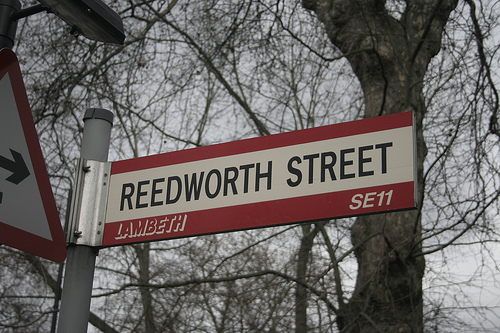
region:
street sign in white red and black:
[103, 128, 420, 246]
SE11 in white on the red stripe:
[328, 183, 405, 219]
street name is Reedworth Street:
[118, 139, 418, 211]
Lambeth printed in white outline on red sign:
[104, 211, 214, 246]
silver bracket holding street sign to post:
[72, 146, 129, 268]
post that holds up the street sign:
[67, 96, 130, 331]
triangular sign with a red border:
[2, 83, 90, 275]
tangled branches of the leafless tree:
[153, 7, 324, 118]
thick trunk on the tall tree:
[325, 237, 449, 330]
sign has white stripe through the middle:
[114, 147, 376, 261]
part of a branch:
[300, 280, 305, 290]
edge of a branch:
[314, 254, 331, 271]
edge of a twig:
[285, 274, 295, 288]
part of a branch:
[301, 285, 315, 330]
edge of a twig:
[283, 273, 290, 283]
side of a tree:
[396, 263, 406, 272]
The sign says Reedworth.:
[113, 161, 278, 210]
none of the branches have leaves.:
[165, 27, 368, 121]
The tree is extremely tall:
[314, 5, 451, 110]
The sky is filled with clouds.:
[145, 26, 373, 123]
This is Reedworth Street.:
[105, 153, 449, 248]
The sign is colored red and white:
[114, 126, 439, 256]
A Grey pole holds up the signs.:
[68, 108, 129, 332]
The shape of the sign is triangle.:
[1, 58, 91, 263]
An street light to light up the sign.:
[20, 5, 137, 85]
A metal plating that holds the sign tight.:
[52, 154, 113, 260]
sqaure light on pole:
[15, 0, 123, 43]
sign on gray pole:
[56, 106, 420, 330]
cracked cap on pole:
[84, 106, 114, 124]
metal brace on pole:
[65, 157, 111, 249]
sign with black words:
[104, 111, 420, 248]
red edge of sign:
[109, 109, 416, 172]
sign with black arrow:
[1, 47, 67, 265]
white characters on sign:
[349, 187, 394, 210]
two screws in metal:
[71, 159, 91, 241]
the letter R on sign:
[101, 178, 133, 220]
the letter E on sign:
[132, 170, 152, 210]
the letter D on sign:
[162, 171, 184, 208]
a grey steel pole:
[26, 82, 138, 331]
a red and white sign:
[68, 100, 426, 267]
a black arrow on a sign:
[1, 140, 45, 198]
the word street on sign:
[281, 126, 393, 191]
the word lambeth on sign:
[98, 201, 194, 246]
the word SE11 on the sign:
[331, 179, 394, 215]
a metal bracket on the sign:
[67, 145, 110, 260]